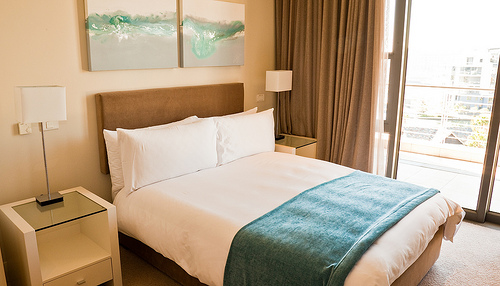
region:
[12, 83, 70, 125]
a white lamp shade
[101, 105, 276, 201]
white pillows on the bed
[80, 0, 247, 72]
two paintings over the bed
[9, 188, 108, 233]
a glass table top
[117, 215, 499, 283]
gray carpet on the ground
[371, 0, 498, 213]
a glass door to the balcony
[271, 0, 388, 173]
a brown curtain on the window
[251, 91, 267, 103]
a white light switch on the wall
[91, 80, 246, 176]
a brown head board on the wall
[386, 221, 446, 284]
a brown foot board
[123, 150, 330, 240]
The linen on the bed is white.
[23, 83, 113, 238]
A lamp is sitting on the nightstand.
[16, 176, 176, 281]
The nightstand is next to the bed.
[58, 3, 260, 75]
The picture is above the bed.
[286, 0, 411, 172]
The curtains are open.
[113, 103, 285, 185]
Four pillows on the bed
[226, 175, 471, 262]
The spread is across the bed.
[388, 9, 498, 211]
The light is shining through the glass doors.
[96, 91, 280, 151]
The headboard is brown.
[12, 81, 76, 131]
The lamp shade is white.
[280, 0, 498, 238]
Sliding door has curtains.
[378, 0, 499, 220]
Glass door is clean.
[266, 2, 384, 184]
Curtains are open.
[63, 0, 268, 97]
Two pictures hang above headboard.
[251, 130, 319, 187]
Nightstand on right side of bed.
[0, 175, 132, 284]
Nightstand on left side of bed.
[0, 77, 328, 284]
Nightstands have lamps on them.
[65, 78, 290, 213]
Wood headboard is attached to wall.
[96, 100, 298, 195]
Four pillows on bed.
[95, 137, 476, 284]
White comforter on bed.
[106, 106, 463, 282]
the bed had white sheets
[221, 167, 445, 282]
the bed has a teal runner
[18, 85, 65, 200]
the lamp is white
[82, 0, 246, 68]
the paintings are white and green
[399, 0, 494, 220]
the patio door is clear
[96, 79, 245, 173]
the backboard is brown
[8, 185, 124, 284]
the side table is white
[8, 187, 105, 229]
side table has a glass top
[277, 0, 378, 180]
the curtain is beige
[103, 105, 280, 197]
the bed has four pillows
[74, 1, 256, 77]
two pieces of artwork on the wall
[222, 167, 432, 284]
teal blanket at end of bed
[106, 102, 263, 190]
four pillows at top of bed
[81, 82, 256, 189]
brown headboard on wall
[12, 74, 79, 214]
lamp on table beside bed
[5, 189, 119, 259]
glass top on bedside table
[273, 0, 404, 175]
long drapes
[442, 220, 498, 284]
carpet on floor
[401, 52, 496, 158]
building outside of glass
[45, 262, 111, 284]
drawer to bedside table